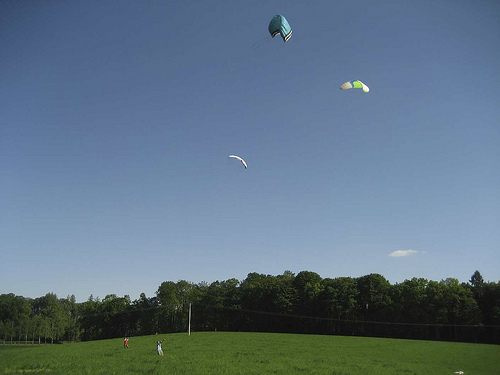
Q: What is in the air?
A: Kites.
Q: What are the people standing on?
A: Grass.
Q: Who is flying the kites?
A: The people in the field.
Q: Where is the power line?
A: On the pole in the field.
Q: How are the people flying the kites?
A: Using the wind.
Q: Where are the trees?
A: Next to the field.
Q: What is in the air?
A: Kites.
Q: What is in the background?
A: Trees.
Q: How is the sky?
A: Clear.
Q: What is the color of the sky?
A: Blue.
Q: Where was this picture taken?
A: Park.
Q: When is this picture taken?
A: Daytime.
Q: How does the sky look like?
A: Clear.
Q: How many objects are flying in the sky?
A: Three.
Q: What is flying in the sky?
A: Parachutes.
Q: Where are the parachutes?
A: Sky.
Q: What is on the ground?
A: Grass.